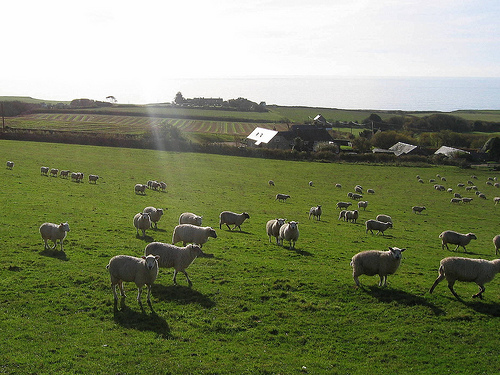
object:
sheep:
[39, 221, 70, 252]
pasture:
[0, 137, 499, 374]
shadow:
[111, 293, 178, 339]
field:
[1, 109, 295, 136]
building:
[246, 123, 288, 149]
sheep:
[132, 212, 151, 238]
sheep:
[87, 174, 99, 184]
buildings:
[373, 134, 427, 159]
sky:
[0, 2, 499, 77]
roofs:
[389, 142, 424, 154]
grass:
[227, 300, 497, 373]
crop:
[223, 120, 230, 133]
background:
[8, 50, 499, 122]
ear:
[60, 222, 63, 226]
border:
[1, 125, 477, 169]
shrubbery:
[0, 127, 182, 152]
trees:
[403, 112, 475, 133]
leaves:
[425, 116, 443, 127]